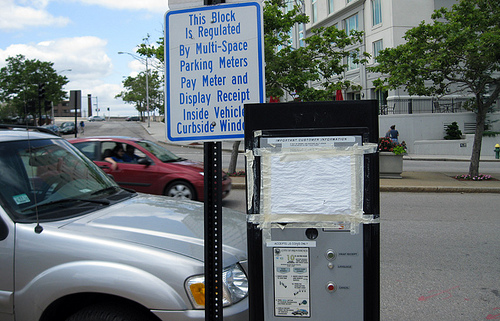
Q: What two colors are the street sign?
A: Blue and white.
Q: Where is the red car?
A: Driving on the street.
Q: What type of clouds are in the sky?
A: White fluffy clouds.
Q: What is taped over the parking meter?
A: White paper.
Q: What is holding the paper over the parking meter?
A: Masking tape.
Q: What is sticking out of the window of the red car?
A: A person's arm.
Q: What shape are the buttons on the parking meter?
A: Round.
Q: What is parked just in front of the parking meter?
A: Silver car.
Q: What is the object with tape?
A: Parking meter.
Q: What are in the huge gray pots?
A: Flowers.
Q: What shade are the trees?
A: Green.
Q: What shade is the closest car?
A: Gray.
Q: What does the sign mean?
A: Pay meters.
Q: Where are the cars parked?
A: Road.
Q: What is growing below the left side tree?
A: Flowers.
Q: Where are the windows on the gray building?
A: In front.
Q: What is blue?
A: Words.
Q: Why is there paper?
A: Machine is broken.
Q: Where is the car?
A: Parked.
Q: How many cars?
A: Two.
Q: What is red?
A: Car.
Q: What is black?
A: Tires.